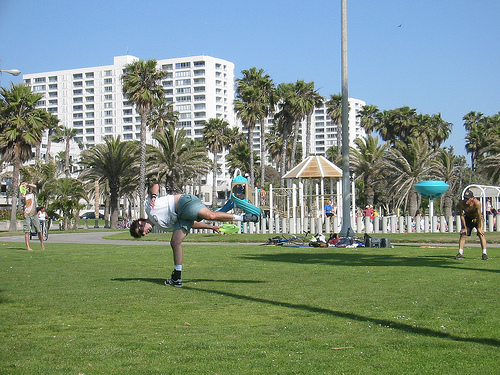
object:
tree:
[121, 57, 166, 223]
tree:
[232, 83, 268, 189]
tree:
[233, 66, 276, 188]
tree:
[273, 79, 324, 214]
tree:
[324, 93, 342, 160]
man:
[129, 184, 260, 288]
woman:
[35, 205, 51, 222]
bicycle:
[23, 217, 51, 241]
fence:
[190, 213, 498, 234]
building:
[3, 55, 238, 211]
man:
[16, 181, 46, 252]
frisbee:
[16, 181, 28, 195]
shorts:
[171, 192, 205, 234]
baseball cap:
[460, 189, 473, 198]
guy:
[450, 187, 487, 261]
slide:
[231, 186, 260, 215]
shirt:
[144, 190, 180, 232]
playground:
[0, 242, 498, 375]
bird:
[396, 22, 403, 31]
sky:
[0, 0, 499, 170]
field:
[0, 243, 498, 375]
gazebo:
[281, 153, 342, 235]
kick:
[200, 204, 263, 227]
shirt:
[35, 211, 47, 222]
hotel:
[235, 97, 369, 175]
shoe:
[162, 270, 183, 288]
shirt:
[22, 186, 39, 216]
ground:
[0, 226, 499, 375]